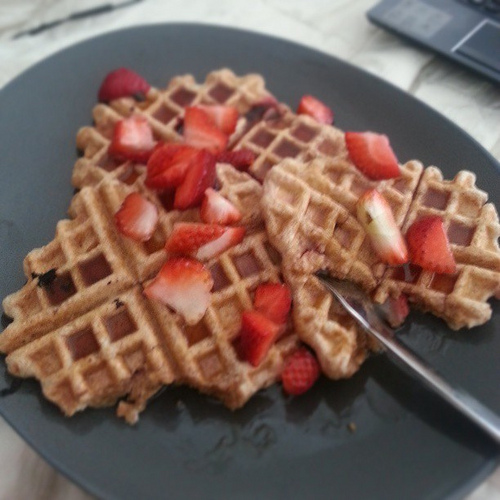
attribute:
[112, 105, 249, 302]
strawberries — chopped, red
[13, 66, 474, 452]
waffles — black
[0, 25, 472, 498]
plate — black, oval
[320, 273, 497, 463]
fork — silver